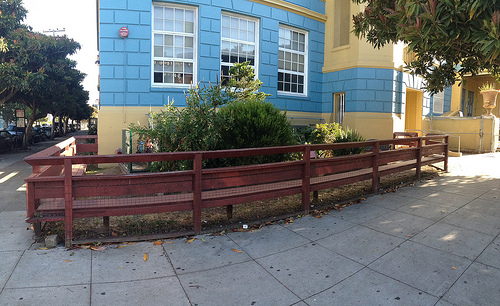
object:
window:
[149, 0, 197, 89]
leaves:
[229, 248, 241, 254]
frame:
[150, 1, 198, 87]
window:
[219, 10, 255, 92]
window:
[278, 25, 307, 90]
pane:
[278, 72, 284, 81]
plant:
[302, 122, 392, 159]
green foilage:
[125, 60, 313, 171]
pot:
[479, 89, 498, 115]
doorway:
[404, 87, 423, 147]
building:
[94, 0, 499, 171]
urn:
[478, 80, 498, 91]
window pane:
[155, 33, 163, 45]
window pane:
[174, 8, 184, 20]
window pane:
[283, 73, 291, 82]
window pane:
[291, 53, 299, 63]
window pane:
[154, 71, 163, 83]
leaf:
[143, 253, 150, 262]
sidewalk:
[1, 156, 500, 306]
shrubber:
[132, 79, 298, 167]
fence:
[23, 131, 453, 246]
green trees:
[347, 0, 499, 98]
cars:
[2, 120, 77, 151]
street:
[1, 118, 57, 228]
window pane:
[291, 52, 299, 62]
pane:
[163, 60, 175, 73]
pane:
[154, 44, 164, 58]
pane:
[298, 34, 306, 45]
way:
[403, 88, 426, 159]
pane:
[153, 72, 163, 84]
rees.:
[0, 0, 108, 156]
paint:
[96, 102, 123, 155]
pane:
[165, 31, 175, 44]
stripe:
[321, 64, 407, 114]